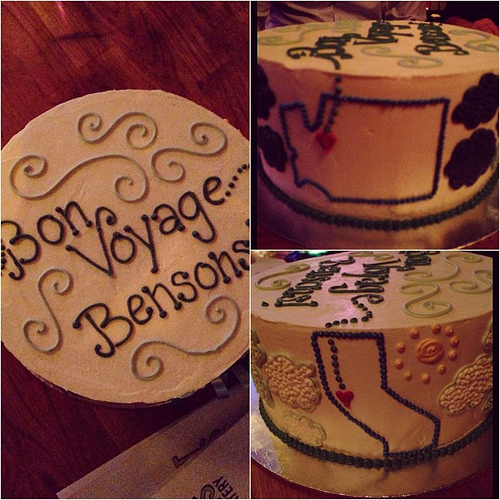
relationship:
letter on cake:
[59, 201, 119, 281] [0, 87, 250, 407]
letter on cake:
[30, 208, 67, 256] [0, 87, 250, 407]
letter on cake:
[71, 300, 130, 360] [0, 87, 250, 407]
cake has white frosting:
[0, 87, 250, 407] [4, 94, 246, 399]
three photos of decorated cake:
[21, 22, 490, 494] [250, 250, 494, 467]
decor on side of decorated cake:
[251, 318, 498, 472] [250, 250, 494, 472]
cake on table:
[7, 87, 237, 374] [18, 17, 178, 64]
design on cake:
[70, 105, 161, 151] [0, 87, 250, 407]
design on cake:
[13, 259, 80, 362] [0, 87, 250, 407]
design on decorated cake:
[391, 324, 458, 385] [250, 250, 494, 472]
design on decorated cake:
[438, 352, 494, 416] [250, 250, 494, 472]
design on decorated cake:
[400, 267, 453, 317] [250, 250, 494, 472]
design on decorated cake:
[405, 252, 492, 317] [250, 250, 494, 472]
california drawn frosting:
[311, 319, 456, 475] [271, 290, 489, 471]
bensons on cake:
[86, 236, 250, 350] [0, 87, 250, 407]